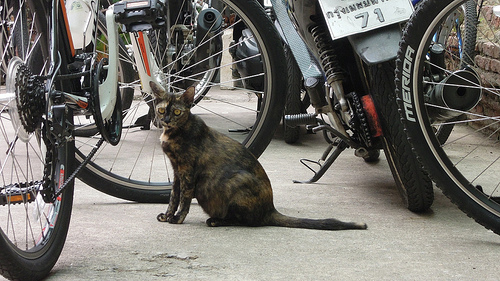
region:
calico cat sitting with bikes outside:
[145, 78, 366, 238]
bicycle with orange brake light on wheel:
[0, 0, 296, 275]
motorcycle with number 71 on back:
[275, 0, 435, 211]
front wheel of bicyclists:
[394, 3, 499, 233]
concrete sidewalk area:
[3, 50, 487, 280]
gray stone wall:
[434, 1, 498, 144]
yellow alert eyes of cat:
[157, 105, 188, 117]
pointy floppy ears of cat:
[149, 79, 197, 104]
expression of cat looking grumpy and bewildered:
[147, 79, 199, 124]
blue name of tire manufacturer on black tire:
[404, 43, 418, 123]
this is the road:
[81, 197, 130, 230]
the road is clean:
[213, 243, 324, 265]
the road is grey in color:
[204, 235, 294, 280]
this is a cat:
[148, 81, 365, 228]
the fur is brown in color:
[203, 145, 233, 181]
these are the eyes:
[150, 103, 190, 123]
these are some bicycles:
[3, 8, 494, 268]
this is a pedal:
[118, 1, 164, 26]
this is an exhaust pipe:
[198, 7, 223, 62]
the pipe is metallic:
[201, 20, 218, 52]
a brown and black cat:
[144, 75, 371, 231]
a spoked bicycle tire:
[393, 0, 499, 235]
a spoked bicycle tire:
[69, 0, 286, 205]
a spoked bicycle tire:
[0, 0, 74, 277]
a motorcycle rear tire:
[351, 49, 433, 213]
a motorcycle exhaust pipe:
[423, 65, 483, 123]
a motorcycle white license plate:
[316, 0, 418, 42]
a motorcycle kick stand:
[286, 142, 348, 184]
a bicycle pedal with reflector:
[0, 180, 38, 202]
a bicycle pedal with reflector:
[119, 0, 164, 35]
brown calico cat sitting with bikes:
[145, 73, 370, 238]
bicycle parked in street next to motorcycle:
[1, 0, 497, 271]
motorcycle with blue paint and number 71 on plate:
[270, 0, 469, 215]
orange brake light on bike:
[133, 30, 162, 101]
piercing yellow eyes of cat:
[158, 105, 186, 117]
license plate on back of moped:
[313, 0, 435, 47]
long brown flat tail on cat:
[270, 213, 370, 233]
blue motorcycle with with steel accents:
[285, 17, 373, 187]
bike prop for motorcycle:
[294, 105, 354, 192]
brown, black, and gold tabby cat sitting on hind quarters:
[148, 71, 369, 236]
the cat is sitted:
[136, 65, 263, 240]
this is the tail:
[271, 207, 360, 234]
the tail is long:
[273, 204, 367, 234]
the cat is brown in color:
[200, 151, 243, 206]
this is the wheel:
[393, 62, 413, 93]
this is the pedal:
[82, 0, 170, 74]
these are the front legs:
[158, 170, 195, 222]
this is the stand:
[288, 135, 343, 179]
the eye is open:
[170, 105, 185, 115]